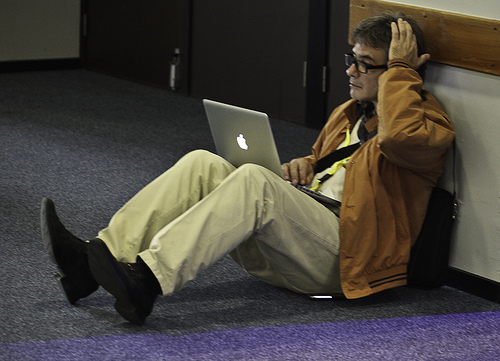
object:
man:
[39, 10, 459, 328]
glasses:
[343, 54, 387, 74]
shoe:
[91, 237, 160, 327]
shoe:
[39, 197, 88, 305]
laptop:
[202, 98, 340, 205]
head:
[344, 10, 426, 102]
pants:
[95, 148, 342, 297]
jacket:
[306, 59, 455, 299]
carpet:
[2, 70, 500, 360]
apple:
[236, 135, 248, 150]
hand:
[388, 18, 430, 66]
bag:
[407, 187, 458, 290]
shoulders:
[417, 89, 458, 169]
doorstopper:
[168, 47, 181, 93]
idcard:
[306, 181, 322, 190]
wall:
[349, 0, 500, 303]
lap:
[205, 162, 313, 232]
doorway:
[80, 0, 349, 131]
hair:
[353, 11, 428, 59]